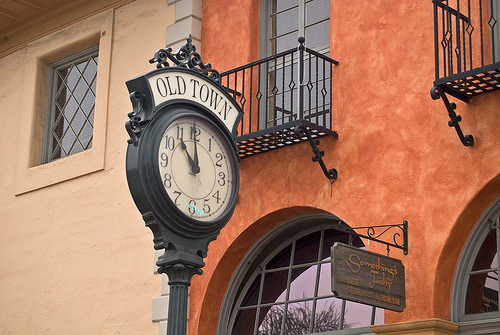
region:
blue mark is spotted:
[179, 197, 208, 212]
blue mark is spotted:
[186, 201, 201, 209]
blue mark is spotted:
[193, 200, 202, 219]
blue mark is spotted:
[187, 200, 200, 219]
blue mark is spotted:
[182, 196, 199, 222]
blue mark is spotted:
[187, 195, 206, 222]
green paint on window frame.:
[258, 8, 268, 48]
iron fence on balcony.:
[286, 57, 331, 97]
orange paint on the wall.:
[373, 57, 413, 122]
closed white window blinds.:
[279, 18, 300, 25]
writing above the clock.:
[159, 76, 222, 101]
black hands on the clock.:
[182, 124, 197, 166]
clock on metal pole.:
[145, 131, 231, 231]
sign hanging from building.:
[327, 260, 412, 295]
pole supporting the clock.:
[163, 279, 190, 333]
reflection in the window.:
[262, 283, 325, 326]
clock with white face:
[145, 109, 245, 229]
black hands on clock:
[172, 122, 211, 177]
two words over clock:
[149, 69, 248, 121]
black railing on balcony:
[241, 43, 341, 158]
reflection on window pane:
[269, 292, 329, 333]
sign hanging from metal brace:
[315, 233, 413, 316]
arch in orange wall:
[247, 194, 316, 226]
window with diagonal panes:
[31, 49, 103, 173]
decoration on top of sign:
[149, 39, 234, 84]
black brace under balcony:
[292, 118, 342, 185]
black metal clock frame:
[119, 28, 250, 333]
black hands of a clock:
[175, 110, 208, 172]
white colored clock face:
[154, 112, 239, 224]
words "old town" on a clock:
[146, 68, 242, 128]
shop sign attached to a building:
[323, 207, 415, 314]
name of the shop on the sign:
[346, 252, 401, 291]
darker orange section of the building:
[191, 0, 499, 333]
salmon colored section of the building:
[3, 0, 161, 332]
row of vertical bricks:
[149, 1, 200, 332]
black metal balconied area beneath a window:
[191, 37, 345, 151]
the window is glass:
[269, 282, 280, 292]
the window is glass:
[272, 280, 279, 298]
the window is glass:
[264, 280, 274, 297]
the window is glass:
[270, 280, 282, 302]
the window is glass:
[273, 290, 281, 301]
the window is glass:
[273, 278, 282, 287]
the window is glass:
[274, 274, 280, 296]